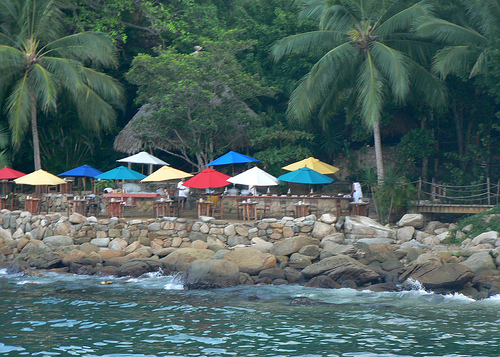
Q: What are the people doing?
A: The people are preparing for customers.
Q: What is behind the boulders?
A: A rock wall.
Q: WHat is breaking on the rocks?
A: The ocean waves.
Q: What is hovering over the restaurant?
A: Coconut palms.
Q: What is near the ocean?
A: Palm tree are near the ocean.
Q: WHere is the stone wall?
A: On the beach.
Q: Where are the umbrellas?
A: At an oceanside bar.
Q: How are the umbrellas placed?
A: The umbrellas are lined up.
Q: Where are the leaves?
A: On trees.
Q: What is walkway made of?
A: Wood and rope.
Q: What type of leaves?
A: Palm.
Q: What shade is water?
A: Dark.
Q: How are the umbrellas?
A: Colorful.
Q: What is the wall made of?
A: Stone.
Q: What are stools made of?
A: Wood.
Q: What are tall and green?
A: Trees.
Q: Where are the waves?
A: In the water.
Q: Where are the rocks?
A: Near the water.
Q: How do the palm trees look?
A: Tall.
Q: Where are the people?
A: Standing by the tables.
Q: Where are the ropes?
A: On the bridge.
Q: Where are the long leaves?
A: On the palm trees.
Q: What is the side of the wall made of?
A: Stone.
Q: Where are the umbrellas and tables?
A: Near the water.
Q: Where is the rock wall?
A: By the water.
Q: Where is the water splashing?
A: On the rocks.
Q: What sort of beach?
A: Rocky.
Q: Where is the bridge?
A: On the right.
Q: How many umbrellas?
A: Eleven.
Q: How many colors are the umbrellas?
A: Five.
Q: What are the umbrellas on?
A: Tables.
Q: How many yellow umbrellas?
A: Three.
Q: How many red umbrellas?
A: Two.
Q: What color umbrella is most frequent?
A: Yellow.